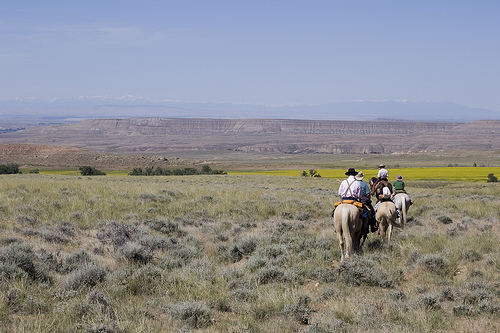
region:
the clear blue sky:
[1, 7, 498, 83]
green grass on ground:
[99, 180, 132, 210]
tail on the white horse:
[339, 214, 351, 249]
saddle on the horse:
[331, 192, 366, 209]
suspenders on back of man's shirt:
[340, 175, 357, 199]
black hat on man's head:
[341, 168, 361, 177]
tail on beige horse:
[382, 208, 403, 229]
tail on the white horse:
[397, 192, 411, 222]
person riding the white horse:
[396, 175, 406, 190]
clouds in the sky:
[95, 24, 153, 49]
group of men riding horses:
[318, 145, 421, 256]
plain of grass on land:
[11, 188, 487, 325]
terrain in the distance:
[20, 123, 477, 135]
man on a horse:
[335, 165, 359, 246]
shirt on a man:
[341, 180, 358, 200]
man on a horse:
[387, 175, 414, 215]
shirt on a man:
[391, 180, 403, 188]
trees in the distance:
[81, 163, 218, 178]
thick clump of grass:
[136, 259, 163, 284]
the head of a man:
[336, 155, 362, 190]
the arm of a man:
[333, 170, 354, 212]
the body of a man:
[330, 154, 388, 221]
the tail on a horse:
[331, 198, 368, 273]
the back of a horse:
[323, 190, 382, 250]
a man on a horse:
[310, 141, 402, 269]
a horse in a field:
[296, 142, 438, 298]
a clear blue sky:
[239, 30, 345, 107]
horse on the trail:
[373, 206, 396, 250]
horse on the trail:
[396, 189, 411, 222]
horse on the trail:
[321, 204, 360, 266]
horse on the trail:
[388, 184, 415, 222]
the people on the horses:
[331, 163, 412, 263]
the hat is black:
[343, 168, 358, 177]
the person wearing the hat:
[332, 166, 379, 232]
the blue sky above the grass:
[1, 0, 498, 331]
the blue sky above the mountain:
[0, 0, 497, 155]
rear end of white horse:
[328, 200, 367, 267]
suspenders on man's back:
[342, 175, 357, 202]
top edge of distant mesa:
[58, 110, 496, 137]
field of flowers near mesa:
[223, 163, 498, 187]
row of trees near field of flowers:
[2, 157, 231, 184]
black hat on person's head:
[342, 162, 361, 179]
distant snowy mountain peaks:
[2, 90, 498, 118]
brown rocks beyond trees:
[90, 151, 205, 165]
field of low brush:
[0, 172, 499, 332]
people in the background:
[334, 137, 468, 278]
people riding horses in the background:
[328, 126, 452, 289]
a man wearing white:
[299, 130, 376, 271]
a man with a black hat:
[318, 154, 380, 257]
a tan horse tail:
[324, 156, 380, 278]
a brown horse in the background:
[329, 157, 379, 275]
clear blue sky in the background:
[67, 22, 473, 114]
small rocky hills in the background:
[91, 99, 438, 156]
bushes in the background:
[73, 153, 263, 196]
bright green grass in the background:
[272, 155, 489, 185]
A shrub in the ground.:
[256, 262, 290, 285]